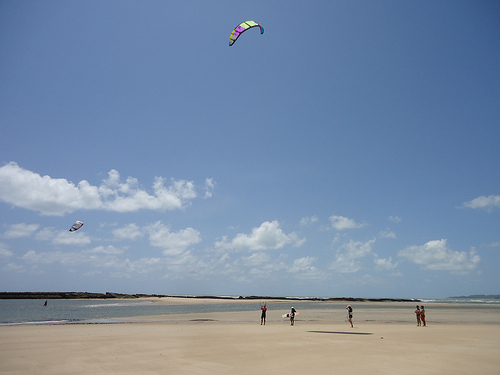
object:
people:
[261, 305, 267, 325]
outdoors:
[0, 0, 500, 369]